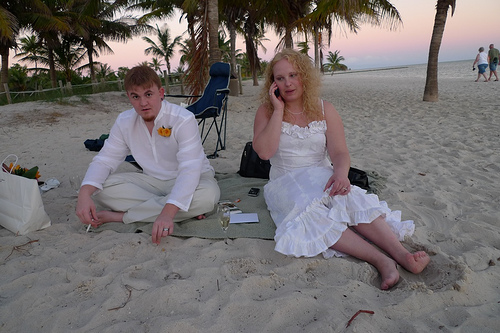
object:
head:
[123, 66, 164, 122]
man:
[73, 64, 221, 245]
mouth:
[140, 107, 153, 112]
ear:
[159, 87, 165, 99]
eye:
[145, 91, 153, 98]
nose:
[139, 97, 149, 107]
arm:
[160, 114, 206, 217]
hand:
[151, 215, 174, 245]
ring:
[162, 227, 169, 231]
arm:
[323, 101, 350, 175]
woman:
[249, 48, 432, 291]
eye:
[289, 71, 297, 78]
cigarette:
[85, 218, 94, 232]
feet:
[376, 257, 401, 291]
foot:
[91, 210, 110, 226]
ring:
[342, 186, 347, 190]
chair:
[185, 60, 232, 160]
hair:
[259, 48, 325, 124]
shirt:
[78, 101, 215, 212]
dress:
[262, 98, 414, 260]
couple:
[471, 42, 500, 83]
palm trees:
[419, 0, 458, 106]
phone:
[274, 82, 281, 99]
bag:
[1, 152, 55, 235]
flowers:
[162, 128, 171, 137]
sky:
[2, 1, 498, 77]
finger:
[152, 225, 158, 243]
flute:
[214, 204, 231, 246]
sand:
[0, 58, 499, 332]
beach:
[0, 65, 499, 332]